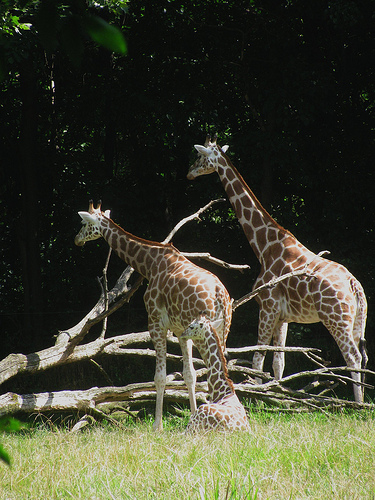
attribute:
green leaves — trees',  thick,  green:
[23, 14, 356, 272]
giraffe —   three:
[68, 198, 202, 311]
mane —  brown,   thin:
[214, 142, 297, 241]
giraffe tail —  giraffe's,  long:
[342, 271, 373, 399]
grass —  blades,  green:
[150, 429, 217, 466]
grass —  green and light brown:
[44, 426, 162, 477]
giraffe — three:
[172, 314, 260, 440]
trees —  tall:
[9, 15, 164, 198]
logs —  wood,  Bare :
[1, 231, 347, 420]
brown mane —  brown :
[228, 160, 330, 269]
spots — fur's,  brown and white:
[154, 263, 189, 305]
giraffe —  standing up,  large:
[184, 138, 370, 402]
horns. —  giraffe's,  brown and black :
[194, 121, 237, 146]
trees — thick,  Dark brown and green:
[0, 4, 375, 335]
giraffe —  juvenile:
[34, 177, 291, 463]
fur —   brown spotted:
[273, 237, 326, 263]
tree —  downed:
[8, 193, 374, 423]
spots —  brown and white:
[275, 247, 331, 283]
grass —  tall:
[73, 433, 289, 490]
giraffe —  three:
[157, 314, 251, 433]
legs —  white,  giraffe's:
[138, 338, 199, 441]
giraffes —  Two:
[186, 133, 368, 404]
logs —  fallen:
[2, 195, 372, 417]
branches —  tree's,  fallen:
[0, 197, 375, 431]